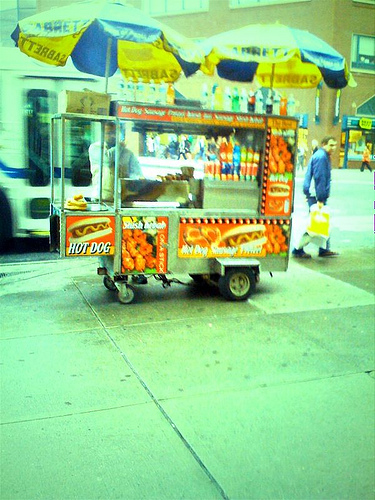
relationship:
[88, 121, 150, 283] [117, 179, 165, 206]
man serving hot dogs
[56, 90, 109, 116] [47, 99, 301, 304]
cardboard box on cart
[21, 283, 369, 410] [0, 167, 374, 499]
spots on ground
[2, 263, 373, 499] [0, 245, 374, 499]
lines on sidewalk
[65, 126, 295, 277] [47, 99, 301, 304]
picture on cart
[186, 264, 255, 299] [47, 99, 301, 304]
wheels on cart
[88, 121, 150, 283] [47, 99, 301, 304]
man behind cart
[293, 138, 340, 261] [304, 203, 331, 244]
man holding bag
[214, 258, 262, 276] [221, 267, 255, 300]
cover on tire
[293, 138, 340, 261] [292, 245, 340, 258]
man has sneakers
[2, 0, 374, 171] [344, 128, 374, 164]
building has window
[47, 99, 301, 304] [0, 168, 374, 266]
cart on street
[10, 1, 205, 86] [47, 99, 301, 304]
sabrett umbrella on cart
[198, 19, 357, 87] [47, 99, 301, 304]
sabrett umbrella on cart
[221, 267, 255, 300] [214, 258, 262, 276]
tire has cover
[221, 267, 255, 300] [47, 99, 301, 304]
tire under cart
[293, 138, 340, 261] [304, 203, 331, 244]
man has bag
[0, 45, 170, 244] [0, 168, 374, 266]
commuter bus on street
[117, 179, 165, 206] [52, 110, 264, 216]
hot dogs in display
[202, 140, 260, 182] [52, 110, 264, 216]
beverage bottles in display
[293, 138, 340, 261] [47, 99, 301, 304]
man next to cart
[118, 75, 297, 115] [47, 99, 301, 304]
beverage bottles on top of cart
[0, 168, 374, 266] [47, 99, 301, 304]
street behind cart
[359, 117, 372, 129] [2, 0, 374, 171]
best buy sign on building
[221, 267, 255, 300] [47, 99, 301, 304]
tire on cart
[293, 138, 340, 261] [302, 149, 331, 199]
man wearing jacket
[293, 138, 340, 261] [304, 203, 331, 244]
man carrying bag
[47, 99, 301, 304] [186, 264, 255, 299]
cart has wheels